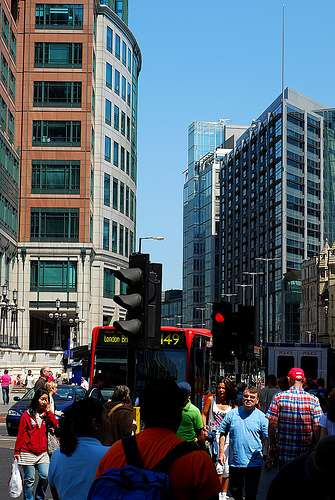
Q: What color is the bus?
A: Red.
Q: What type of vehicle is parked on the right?
A: Police van.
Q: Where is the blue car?
A: Beside the bus.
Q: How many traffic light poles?
A: 2.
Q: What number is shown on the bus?
A: 149.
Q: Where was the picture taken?
A: On a city street.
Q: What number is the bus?
A: 149.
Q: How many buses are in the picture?
A: 1.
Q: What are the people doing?
A: Walking.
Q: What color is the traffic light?
A: Red.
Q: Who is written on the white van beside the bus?
A: Police.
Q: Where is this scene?
A: Downtown.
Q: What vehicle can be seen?
A: Bus.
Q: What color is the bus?
A: Red.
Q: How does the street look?
A: Busy.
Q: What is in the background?
A: Tall buildings.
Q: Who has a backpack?
A: Man in red shirt.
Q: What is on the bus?
A: 149.